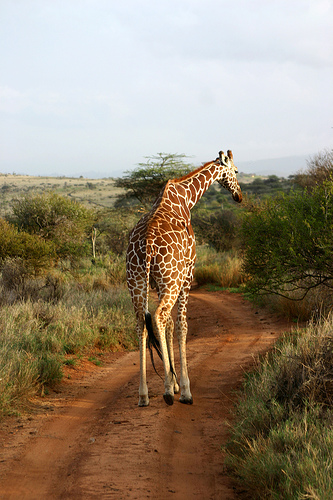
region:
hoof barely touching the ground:
[162, 391, 175, 407]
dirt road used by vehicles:
[0, 288, 305, 496]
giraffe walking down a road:
[125, 148, 244, 406]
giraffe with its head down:
[125, 149, 242, 407]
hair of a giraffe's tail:
[143, 312, 175, 382]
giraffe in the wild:
[0, 150, 331, 499]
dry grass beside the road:
[215, 304, 331, 498]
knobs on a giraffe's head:
[218, 147, 236, 160]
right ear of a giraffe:
[222, 153, 230, 168]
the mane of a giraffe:
[146, 157, 220, 224]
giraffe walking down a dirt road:
[128, 151, 236, 405]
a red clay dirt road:
[17, 287, 272, 499]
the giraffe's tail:
[144, 249, 153, 374]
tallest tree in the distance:
[116, 150, 199, 209]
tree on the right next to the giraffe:
[245, 179, 331, 302]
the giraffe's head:
[216, 152, 242, 202]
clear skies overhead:
[2, 3, 327, 175]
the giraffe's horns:
[217, 149, 233, 162]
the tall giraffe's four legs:
[133, 291, 191, 406]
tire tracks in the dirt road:
[13, 287, 262, 498]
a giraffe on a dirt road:
[125, 147, 243, 403]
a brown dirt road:
[30, 415, 192, 486]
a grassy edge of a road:
[226, 333, 304, 489]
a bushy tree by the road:
[235, 169, 330, 304]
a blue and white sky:
[15, 1, 295, 142]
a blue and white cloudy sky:
[3, 4, 326, 123]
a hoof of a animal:
[162, 388, 176, 412]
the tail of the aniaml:
[142, 254, 160, 369]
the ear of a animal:
[215, 147, 236, 166]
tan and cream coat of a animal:
[146, 207, 194, 265]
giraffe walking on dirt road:
[110, 142, 250, 411]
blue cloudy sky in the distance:
[12, 27, 296, 135]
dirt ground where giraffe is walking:
[17, 416, 209, 497]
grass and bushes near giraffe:
[15, 198, 111, 342]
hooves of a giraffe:
[129, 386, 205, 410]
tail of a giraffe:
[136, 241, 167, 364]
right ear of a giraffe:
[216, 151, 229, 167]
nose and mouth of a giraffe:
[228, 187, 247, 202]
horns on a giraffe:
[217, 148, 234, 160]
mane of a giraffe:
[170, 159, 218, 180]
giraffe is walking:
[120, 127, 244, 449]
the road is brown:
[61, 331, 208, 495]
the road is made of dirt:
[38, 296, 259, 487]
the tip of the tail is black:
[118, 293, 178, 384]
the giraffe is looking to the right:
[181, 139, 259, 217]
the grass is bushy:
[4, 254, 124, 357]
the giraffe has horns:
[219, 143, 238, 162]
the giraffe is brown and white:
[104, 144, 252, 403]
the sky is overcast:
[11, 23, 318, 163]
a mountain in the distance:
[230, 146, 317, 171]